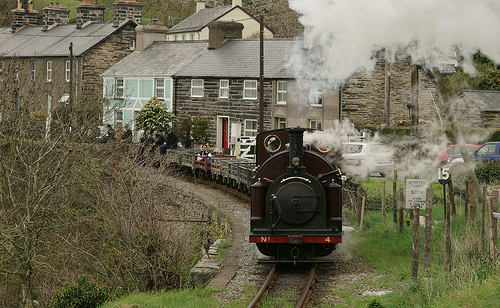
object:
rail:
[246, 260, 318, 307]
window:
[243, 88, 257, 97]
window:
[217, 88, 229, 96]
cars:
[447, 141, 499, 164]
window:
[114, 78, 124, 87]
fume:
[301, 96, 499, 188]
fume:
[283, 0, 499, 112]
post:
[410, 202, 420, 278]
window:
[191, 88, 203, 98]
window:
[218, 79, 232, 88]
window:
[282, 82, 288, 92]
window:
[65, 70, 71, 82]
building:
[97, 0, 446, 161]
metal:
[293, 264, 321, 307]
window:
[190, 79, 205, 86]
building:
[0, 0, 142, 122]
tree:
[132, 97, 173, 153]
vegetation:
[100, 286, 223, 308]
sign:
[402, 179, 427, 210]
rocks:
[237, 271, 249, 285]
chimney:
[285, 125, 308, 152]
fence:
[356, 168, 499, 278]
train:
[126, 125, 347, 265]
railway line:
[295, 265, 319, 307]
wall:
[172, 78, 271, 155]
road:
[124, 155, 384, 307]